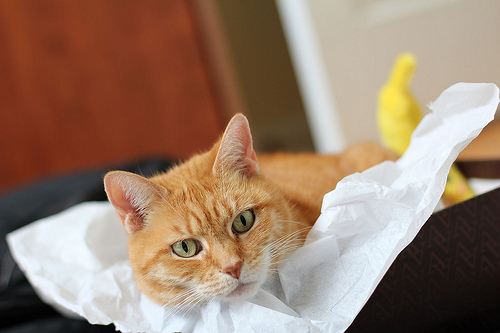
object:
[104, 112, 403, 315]
cat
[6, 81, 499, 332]
bag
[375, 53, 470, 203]
toy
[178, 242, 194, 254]
pupils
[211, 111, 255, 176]
ear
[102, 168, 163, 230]
ear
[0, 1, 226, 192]
door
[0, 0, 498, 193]
background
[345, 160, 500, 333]
furniture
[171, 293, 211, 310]
whisker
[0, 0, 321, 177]
door way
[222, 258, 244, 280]
nose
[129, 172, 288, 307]
face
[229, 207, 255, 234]
eye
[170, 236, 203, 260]
eye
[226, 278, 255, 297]
mouth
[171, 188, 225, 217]
fur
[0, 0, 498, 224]
distance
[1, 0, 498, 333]
picture